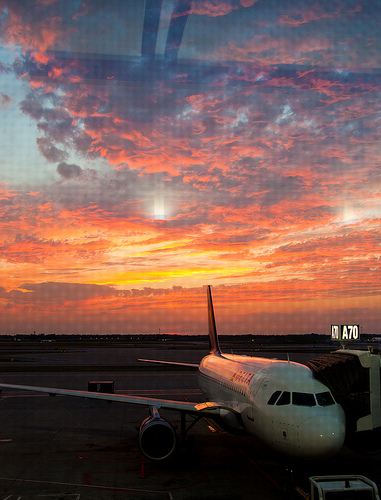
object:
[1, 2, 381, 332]
sky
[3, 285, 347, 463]
plane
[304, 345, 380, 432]
terminal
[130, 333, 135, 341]
lights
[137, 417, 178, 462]
engine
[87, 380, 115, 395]
cart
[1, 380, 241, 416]
wing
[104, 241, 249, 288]
sunlight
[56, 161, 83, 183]
clouds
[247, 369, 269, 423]
door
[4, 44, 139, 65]
lines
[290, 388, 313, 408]
windows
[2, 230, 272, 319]
sunset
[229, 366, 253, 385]
logo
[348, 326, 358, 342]
number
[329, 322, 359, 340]
sign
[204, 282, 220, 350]
tail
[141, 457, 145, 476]
cone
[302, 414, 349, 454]
nose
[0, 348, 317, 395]
runway